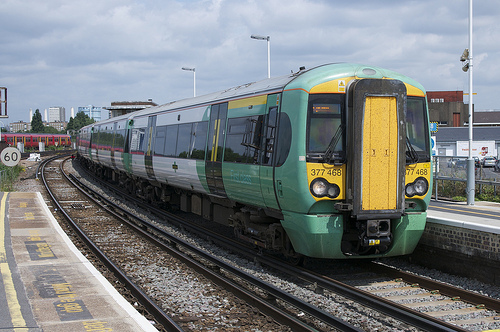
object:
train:
[75, 63, 433, 262]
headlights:
[311, 177, 341, 199]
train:
[1, 134, 70, 147]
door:
[360, 94, 402, 213]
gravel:
[353, 269, 492, 329]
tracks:
[60, 149, 498, 329]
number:
[4, 152, 18, 162]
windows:
[224, 115, 262, 163]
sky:
[3, 1, 499, 126]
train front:
[300, 62, 435, 263]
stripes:
[145, 123, 154, 165]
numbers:
[311, 168, 341, 176]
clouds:
[1, 5, 499, 124]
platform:
[426, 197, 499, 264]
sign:
[430, 121, 439, 132]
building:
[433, 126, 499, 169]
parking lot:
[433, 156, 499, 189]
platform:
[2, 190, 153, 332]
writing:
[58, 296, 85, 314]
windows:
[25, 137, 28, 141]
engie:
[233, 206, 292, 251]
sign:
[1, 147, 22, 167]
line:
[2, 279, 25, 331]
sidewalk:
[0, 189, 158, 331]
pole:
[466, 0, 473, 203]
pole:
[267, 36, 270, 79]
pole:
[194, 71, 196, 97]